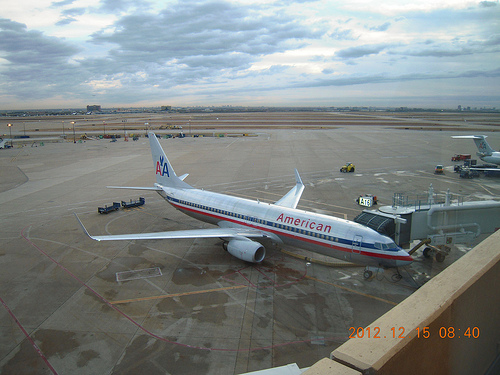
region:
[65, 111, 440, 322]
This is an airplane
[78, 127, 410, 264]
American Airlines intercontinental jet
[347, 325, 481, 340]
Timestamp indicates a December morning.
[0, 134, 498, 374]
Tarmac where airport operations are conducted.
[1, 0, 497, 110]
cloudy, overcast day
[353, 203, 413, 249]
temporary corridor to load passengers into plane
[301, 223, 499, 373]
elevated area above tarmac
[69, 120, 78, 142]
lights on the edge of tarmac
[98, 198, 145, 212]
luggage loading vehicle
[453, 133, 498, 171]
airplane at the edge of the tarmac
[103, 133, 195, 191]
tail section of airplane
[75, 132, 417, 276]
White airplane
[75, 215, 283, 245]
Right wing of the airplane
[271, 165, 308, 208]
Left wing of the airplane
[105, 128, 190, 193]
Tail of the airplane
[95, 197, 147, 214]
Luggage carriers behind the airplane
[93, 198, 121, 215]
Luggage carrier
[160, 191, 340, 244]
Right panel of airplane windows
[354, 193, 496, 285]
Small building next to the airplane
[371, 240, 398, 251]
Front window of the airplane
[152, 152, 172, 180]
Logo of the airline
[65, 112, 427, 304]
american plane on the runway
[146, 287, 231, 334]
wet spots on the runway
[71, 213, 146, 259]
wing of the plane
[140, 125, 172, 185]
tail of the plane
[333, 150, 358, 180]
vehicle on the runway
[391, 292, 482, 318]
brown and tan wall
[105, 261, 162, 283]
white square on the rumway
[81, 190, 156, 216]
luggage rack cars on the runway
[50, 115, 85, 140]
lights on the runway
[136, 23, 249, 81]
dark fluffy dreary clouds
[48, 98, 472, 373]
the plane at the airport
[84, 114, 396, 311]
the airplane is silver